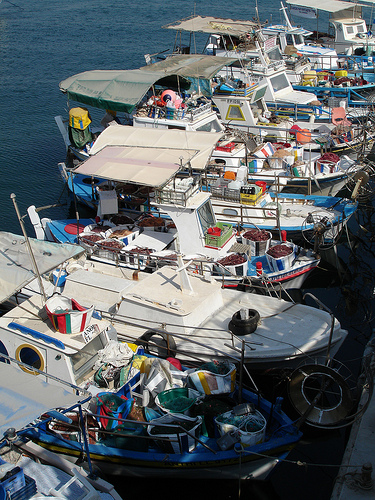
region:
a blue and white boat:
[2, 301, 298, 475]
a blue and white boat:
[0, 424, 124, 494]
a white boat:
[2, 240, 341, 394]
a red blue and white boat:
[31, 202, 317, 290]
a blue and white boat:
[56, 165, 356, 233]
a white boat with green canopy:
[55, 66, 352, 194]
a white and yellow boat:
[203, 86, 357, 151]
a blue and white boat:
[259, 21, 372, 69]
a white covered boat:
[288, 1, 373, 53]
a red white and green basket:
[42, 296, 95, 334]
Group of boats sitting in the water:
[49, 66, 367, 475]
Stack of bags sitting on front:
[81, 339, 264, 455]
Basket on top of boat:
[35, 293, 106, 342]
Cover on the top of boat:
[50, 64, 216, 107]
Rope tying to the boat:
[257, 321, 373, 375]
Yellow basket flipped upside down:
[61, 102, 106, 128]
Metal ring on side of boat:
[139, 316, 184, 350]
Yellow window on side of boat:
[232, 100, 259, 124]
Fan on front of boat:
[332, 153, 366, 183]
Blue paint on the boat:
[65, 420, 213, 483]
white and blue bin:
[261, 238, 301, 275]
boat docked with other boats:
[22, 180, 327, 294]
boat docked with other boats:
[0, 286, 303, 478]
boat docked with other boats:
[1, 220, 355, 377]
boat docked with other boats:
[296, 4, 373, 58]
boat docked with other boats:
[129, 46, 373, 164]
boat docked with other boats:
[0, 343, 127, 499]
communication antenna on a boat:
[162, 246, 201, 301]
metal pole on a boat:
[5, 182, 70, 327]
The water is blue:
[24, 15, 102, 59]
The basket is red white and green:
[47, 289, 94, 334]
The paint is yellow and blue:
[31, 429, 132, 462]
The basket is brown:
[233, 305, 260, 334]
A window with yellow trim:
[12, 340, 46, 375]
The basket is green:
[203, 218, 233, 249]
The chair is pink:
[326, 102, 354, 134]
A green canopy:
[56, 67, 188, 106]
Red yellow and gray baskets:
[223, 178, 268, 205]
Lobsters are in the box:
[262, 239, 296, 271]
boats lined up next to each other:
[131, 45, 329, 243]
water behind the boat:
[4, 76, 50, 131]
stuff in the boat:
[252, 139, 291, 157]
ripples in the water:
[30, 17, 100, 56]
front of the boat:
[203, 369, 312, 459]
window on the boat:
[220, 92, 246, 118]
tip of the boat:
[260, 409, 310, 446]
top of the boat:
[53, 51, 163, 114]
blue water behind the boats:
[7, 17, 78, 49]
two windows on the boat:
[338, 19, 369, 39]